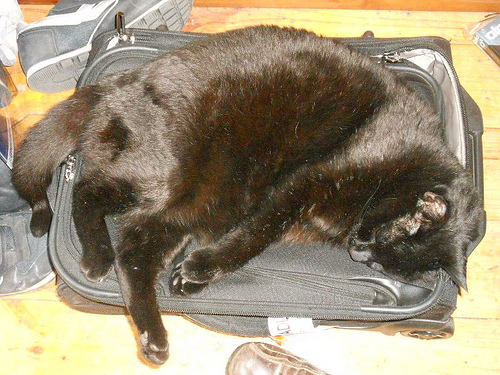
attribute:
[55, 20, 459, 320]
suitcase — black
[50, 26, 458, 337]
cat — black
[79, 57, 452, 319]
cat — black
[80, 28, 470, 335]
cat — black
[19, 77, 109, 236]
tail — black